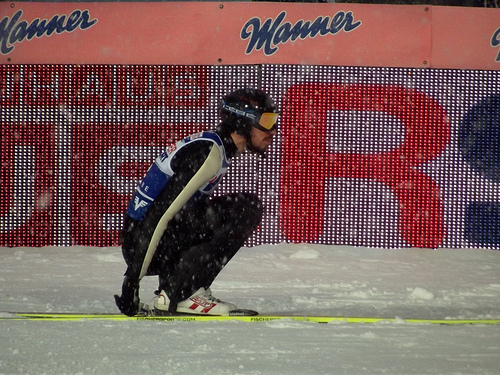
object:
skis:
[2, 313, 499, 327]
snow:
[7, 248, 500, 362]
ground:
[0, 247, 494, 375]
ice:
[0, 248, 500, 375]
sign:
[3, 5, 499, 247]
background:
[5, 6, 500, 248]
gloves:
[113, 278, 141, 317]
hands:
[113, 272, 140, 317]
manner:
[237, 10, 363, 57]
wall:
[7, 8, 499, 245]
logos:
[0, 9, 97, 54]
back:
[120, 126, 207, 244]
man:
[112, 88, 278, 318]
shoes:
[154, 286, 232, 316]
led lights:
[341, 228, 344, 231]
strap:
[223, 104, 256, 119]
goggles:
[221, 104, 279, 132]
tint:
[259, 113, 279, 129]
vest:
[123, 131, 229, 222]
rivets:
[218, 58, 223, 63]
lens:
[259, 112, 278, 130]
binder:
[167, 244, 203, 312]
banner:
[0, 2, 500, 67]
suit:
[121, 130, 263, 300]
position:
[112, 88, 282, 318]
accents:
[189, 294, 216, 313]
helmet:
[221, 88, 278, 136]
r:
[278, 82, 451, 250]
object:
[11, 312, 499, 326]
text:
[250, 317, 309, 322]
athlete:
[112, 88, 278, 316]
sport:
[3, 5, 496, 365]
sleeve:
[129, 141, 225, 285]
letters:
[5, 70, 497, 238]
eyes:
[263, 119, 273, 125]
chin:
[247, 143, 269, 153]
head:
[219, 88, 279, 155]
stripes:
[200, 303, 216, 313]